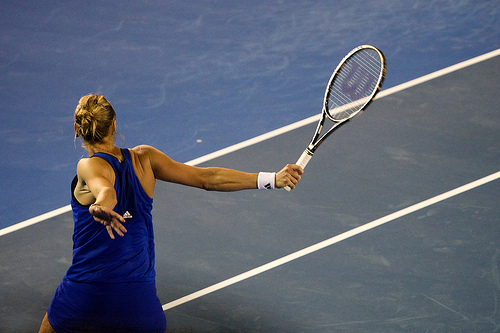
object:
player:
[32, 93, 304, 333]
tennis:
[1, 1, 499, 333]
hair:
[70, 92, 125, 153]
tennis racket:
[282, 45, 387, 193]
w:
[337, 60, 379, 102]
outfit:
[46, 147, 169, 331]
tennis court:
[0, 0, 499, 332]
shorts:
[41, 280, 170, 331]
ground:
[0, 0, 499, 333]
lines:
[160, 170, 500, 310]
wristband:
[255, 171, 278, 191]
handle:
[275, 151, 315, 192]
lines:
[0, 49, 499, 237]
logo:
[121, 210, 135, 221]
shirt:
[64, 148, 156, 284]